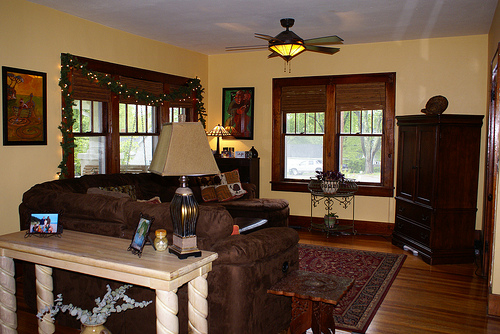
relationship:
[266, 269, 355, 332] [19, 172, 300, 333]
end table next to couch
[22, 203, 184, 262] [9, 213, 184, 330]
photos on table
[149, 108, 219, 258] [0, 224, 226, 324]
lamp on table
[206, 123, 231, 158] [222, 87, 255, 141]
lamp in front of frame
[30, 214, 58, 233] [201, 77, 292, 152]
photos in frame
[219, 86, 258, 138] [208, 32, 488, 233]
painting on wall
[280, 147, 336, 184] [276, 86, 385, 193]
car outside of window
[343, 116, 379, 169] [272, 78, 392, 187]
tree outside of window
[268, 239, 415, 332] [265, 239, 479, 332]
rug on floor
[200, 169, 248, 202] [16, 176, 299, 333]
pillow on couch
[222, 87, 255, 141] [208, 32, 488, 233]
frame on wall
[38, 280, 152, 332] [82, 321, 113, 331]
floral arrangment in vase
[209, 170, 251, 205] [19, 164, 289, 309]
pillow on couch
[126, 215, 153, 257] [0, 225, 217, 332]
picture on table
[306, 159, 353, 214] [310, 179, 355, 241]
plant on stand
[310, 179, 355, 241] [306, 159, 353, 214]
stand for a plant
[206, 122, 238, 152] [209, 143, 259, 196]
lamp on a desk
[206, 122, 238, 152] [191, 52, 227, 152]
lamp in a corner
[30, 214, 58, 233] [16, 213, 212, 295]
photos on a table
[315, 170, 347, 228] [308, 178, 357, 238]
plant on a stand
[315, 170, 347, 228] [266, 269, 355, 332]
plant on a end table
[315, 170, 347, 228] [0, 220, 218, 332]
plant on a stand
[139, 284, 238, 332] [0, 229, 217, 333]
legs on stand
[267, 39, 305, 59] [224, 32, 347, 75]
light on fan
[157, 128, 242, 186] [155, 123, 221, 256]
tan shade on lamp